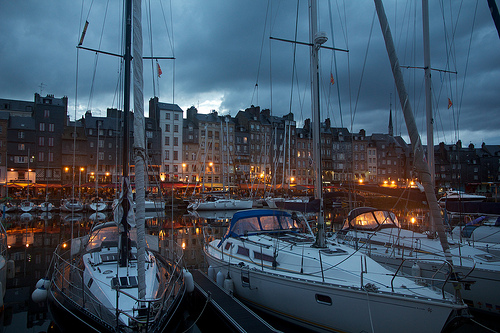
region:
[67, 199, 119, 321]
Sail boat docked at marina.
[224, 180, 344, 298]
Sail boat docked at marina.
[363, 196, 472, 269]
Sail boat docked at marina.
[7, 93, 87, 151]
Large dark building in background.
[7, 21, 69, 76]
Clouds in sky in distance.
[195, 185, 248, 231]
White sail boat docked in water.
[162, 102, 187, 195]
Tall white building in background.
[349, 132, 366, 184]
Tall brown building in distance.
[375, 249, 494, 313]
Silver railing on front of boat.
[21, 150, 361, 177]
Many lights on buildings in background.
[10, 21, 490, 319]
The boats are parked close together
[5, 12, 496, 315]
The boats have very tall masts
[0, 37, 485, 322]
The boats are mostly sailboats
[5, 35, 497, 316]
The boats are in a marina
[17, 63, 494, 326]
The boats are close to the city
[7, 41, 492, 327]
The boats are for having fun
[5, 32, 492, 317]
The boats are owned by rich people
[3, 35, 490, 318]
The owners have parked their boats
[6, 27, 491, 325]
The boats are floating in the water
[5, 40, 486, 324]
The boats are all seaworthy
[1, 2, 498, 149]
The sky has many clouds.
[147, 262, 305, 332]
The walkway is grey.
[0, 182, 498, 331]
Group of boats are docked.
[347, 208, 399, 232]
Windows are lit up.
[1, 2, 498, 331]
Boats are docked.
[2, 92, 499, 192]
Row of buildings are lit up with light.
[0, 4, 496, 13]
The boats are sitting at the dock.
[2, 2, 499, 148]
The sky has a blueish hue.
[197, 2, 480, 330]
Boat is painted white.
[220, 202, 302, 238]
Blue material is on boat.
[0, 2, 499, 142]
gray clouds in sky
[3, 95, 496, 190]
rows of tall builings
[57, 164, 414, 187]
yellow glowing street lights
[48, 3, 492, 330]
docked sailboats with sails down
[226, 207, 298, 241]
blue cover on windows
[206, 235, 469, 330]
white body of boat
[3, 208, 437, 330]
surface of calm water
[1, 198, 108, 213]
sterns of docked boats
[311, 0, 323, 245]
sail pole on boat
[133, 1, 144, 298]
rolled up white canvas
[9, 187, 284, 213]
boats docked on the water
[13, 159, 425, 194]
lights in front of buildings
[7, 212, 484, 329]
a rows of boats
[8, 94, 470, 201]
row of tall buildings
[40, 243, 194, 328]
a silver railing around a boat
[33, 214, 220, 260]
lights reflecting in the water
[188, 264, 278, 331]
a walkway between boats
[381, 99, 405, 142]
a tower in the distance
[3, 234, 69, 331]
buildings reflected in the water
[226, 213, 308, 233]
three windows on the top of a boat